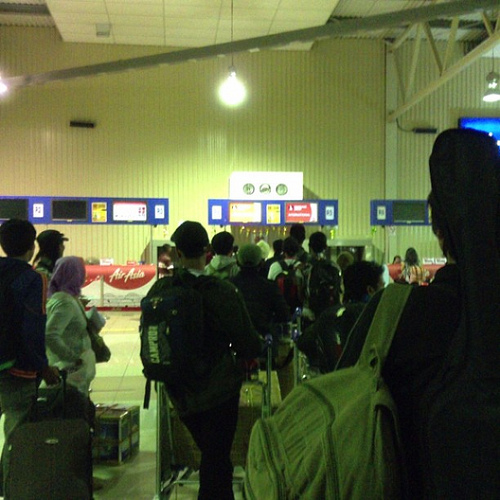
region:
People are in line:
[131, 195, 415, 464]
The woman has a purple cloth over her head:
[46, 251, 99, 296]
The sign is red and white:
[82, 242, 166, 317]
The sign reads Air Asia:
[96, 253, 154, 322]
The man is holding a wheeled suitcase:
[21, 360, 86, 498]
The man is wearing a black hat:
[149, 215, 213, 258]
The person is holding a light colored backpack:
[230, 244, 430, 498]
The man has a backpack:
[134, 265, 222, 383]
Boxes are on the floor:
[84, 399, 146, 474]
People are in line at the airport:
[152, 218, 348, 455]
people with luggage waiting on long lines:
[12, 25, 490, 490]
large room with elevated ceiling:
[10, 11, 482, 486]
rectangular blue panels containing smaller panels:
[1, 195, 426, 225]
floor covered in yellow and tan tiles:
[65, 306, 165, 493]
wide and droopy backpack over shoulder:
[245, 261, 425, 492]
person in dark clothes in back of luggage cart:
[137, 217, 272, 494]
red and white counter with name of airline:
[77, 265, 152, 305]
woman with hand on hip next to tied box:
[45, 251, 140, 461]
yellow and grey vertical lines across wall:
[1, 27, 497, 278]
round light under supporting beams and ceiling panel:
[0, 0, 496, 115]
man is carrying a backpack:
[97, 219, 244, 411]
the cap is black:
[157, 210, 214, 272]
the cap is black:
[150, 205, 274, 290]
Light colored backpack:
[239, 282, 426, 499]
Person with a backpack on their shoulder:
[246, 125, 498, 498]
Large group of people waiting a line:
[3, 127, 498, 499]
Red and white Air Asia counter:
[84, 260, 156, 309]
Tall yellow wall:
[2, 28, 499, 268]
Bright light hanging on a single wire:
[211, 1, 250, 107]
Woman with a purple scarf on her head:
[46, 254, 103, 391]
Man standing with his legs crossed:
[140, 219, 250, 498]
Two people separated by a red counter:
[388, 244, 440, 283]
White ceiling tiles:
[46, 0, 339, 50]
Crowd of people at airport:
[1, 126, 498, 497]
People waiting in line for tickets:
[2, 125, 499, 497]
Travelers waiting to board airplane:
[3, 127, 498, 497]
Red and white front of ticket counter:
[77, 263, 159, 310]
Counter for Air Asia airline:
[78, 263, 158, 306]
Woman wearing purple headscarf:
[43, 254, 110, 399]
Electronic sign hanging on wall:
[1, 194, 169, 226]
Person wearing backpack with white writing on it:
[138, 218, 266, 498]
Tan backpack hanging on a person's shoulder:
[242, 280, 415, 497]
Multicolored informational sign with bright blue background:
[205, 199, 338, 226]